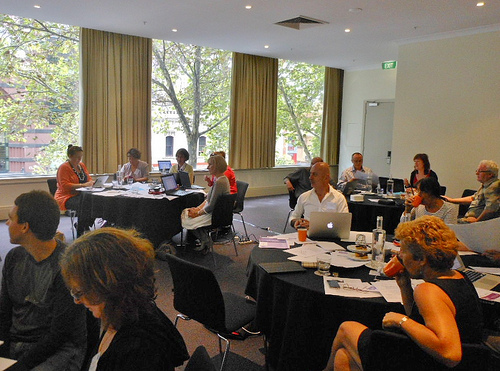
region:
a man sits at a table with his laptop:
[289, 158, 354, 241]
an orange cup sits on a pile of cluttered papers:
[291, 228, 312, 243]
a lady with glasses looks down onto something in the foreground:
[53, 223, 166, 369]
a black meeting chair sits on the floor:
[161, 248, 260, 369]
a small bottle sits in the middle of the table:
[366, 210, 388, 264]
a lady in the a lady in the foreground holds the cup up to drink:
[319, 215, 489, 368]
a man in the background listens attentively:
[439, 156, 498, 224]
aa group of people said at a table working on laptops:
[50, 138, 255, 227]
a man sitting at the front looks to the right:
[2, 184, 66, 365]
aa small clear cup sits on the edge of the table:
[311, 253, 339, 277]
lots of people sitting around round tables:
[25, 108, 475, 348]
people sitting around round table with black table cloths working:
[45, 126, 242, 261]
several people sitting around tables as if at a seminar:
[25, 132, 466, 352]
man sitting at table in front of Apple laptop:
[295, 157, 353, 240]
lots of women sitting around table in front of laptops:
[45, 122, 237, 272]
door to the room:
[356, 85, 401, 183]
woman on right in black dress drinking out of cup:
[372, 213, 473, 365]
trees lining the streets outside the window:
[0, 70, 318, 167]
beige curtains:
[65, 28, 337, 169]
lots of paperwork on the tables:
[73, 136, 446, 316]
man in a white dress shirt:
[287, 158, 354, 230]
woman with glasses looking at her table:
[55, 225, 192, 370]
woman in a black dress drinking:
[350, 212, 485, 369]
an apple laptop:
[301, 207, 355, 244]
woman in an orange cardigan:
[46, 137, 98, 216]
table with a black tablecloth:
[233, 220, 498, 366]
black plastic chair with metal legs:
[153, 249, 278, 369]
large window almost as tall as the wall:
[141, 33, 237, 173]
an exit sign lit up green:
[369, 50, 409, 72]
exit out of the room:
[351, 97, 401, 197]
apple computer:
[305, 208, 359, 240]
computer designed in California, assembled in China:
[303, 207, 358, 242]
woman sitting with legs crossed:
[323, 213, 493, 369]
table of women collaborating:
[44, 140, 252, 250]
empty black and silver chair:
[162, 246, 279, 369]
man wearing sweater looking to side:
[0, 190, 109, 369]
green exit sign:
[377, 57, 399, 74]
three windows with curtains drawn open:
[1, 15, 351, 184]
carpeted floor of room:
[1, 188, 412, 369]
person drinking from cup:
[401, 178, 458, 224]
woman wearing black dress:
[323, 217, 481, 369]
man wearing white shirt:
[286, 159, 346, 227]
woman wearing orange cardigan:
[52, 145, 94, 230]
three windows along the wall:
[3, 22, 323, 177]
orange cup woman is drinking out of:
[378, 252, 400, 279]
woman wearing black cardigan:
[56, 229, 182, 369]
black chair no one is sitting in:
[165, 252, 260, 367]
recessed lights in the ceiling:
[27, 1, 487, 54]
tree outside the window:
[10, 29, 320, 169]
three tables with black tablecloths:
[45, 169, 498, 340]